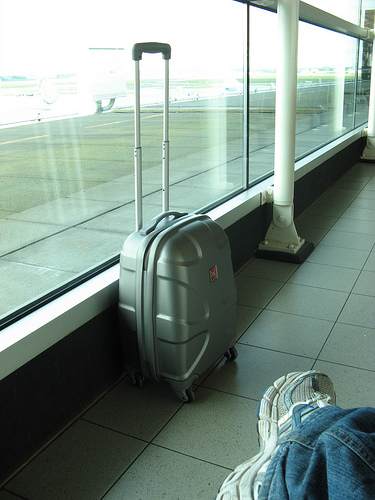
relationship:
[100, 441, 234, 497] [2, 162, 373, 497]
tile on floor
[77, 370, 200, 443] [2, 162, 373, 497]
tile on floor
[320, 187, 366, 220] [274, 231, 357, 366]
tile on floor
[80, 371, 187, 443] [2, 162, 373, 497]
tile on floor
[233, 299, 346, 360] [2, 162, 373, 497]
tile on floor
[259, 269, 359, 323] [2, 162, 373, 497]
tile on floor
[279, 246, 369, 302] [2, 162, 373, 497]
tile on floor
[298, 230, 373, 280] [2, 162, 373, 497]
tile on floor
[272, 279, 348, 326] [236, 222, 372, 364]
while tile on floor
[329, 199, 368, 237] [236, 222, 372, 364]
while tile on floor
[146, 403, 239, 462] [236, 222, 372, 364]
while tile on floor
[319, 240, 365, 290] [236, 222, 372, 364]
while tile on floor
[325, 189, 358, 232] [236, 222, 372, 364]
white tile on floor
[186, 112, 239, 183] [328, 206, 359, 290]
tile on floor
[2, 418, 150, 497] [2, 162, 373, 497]
tile on floor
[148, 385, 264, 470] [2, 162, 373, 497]
tile on floor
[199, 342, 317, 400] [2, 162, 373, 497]
tile on floor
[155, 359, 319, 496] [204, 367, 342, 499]
side of sneaker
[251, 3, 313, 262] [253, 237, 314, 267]
pole bolted in base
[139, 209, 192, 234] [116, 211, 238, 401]
handle on top of luggage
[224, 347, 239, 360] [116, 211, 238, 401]
wheel on bottom of luggage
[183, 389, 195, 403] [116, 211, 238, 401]
wheel on bottom of luggage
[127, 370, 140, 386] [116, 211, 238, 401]
wheel on bottom of luggage